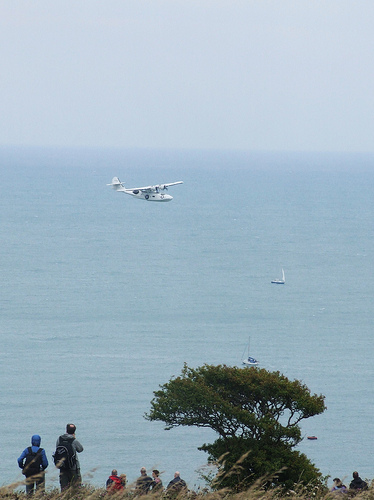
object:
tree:
[146, 357, 327, 447]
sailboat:
[270, 266, 287, 285]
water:
[1, 148, 371, 492]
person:
[14, 436, 46, 498]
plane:
[104, 174, 185, 206]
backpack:
[22, 445, 47, 478]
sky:
[1, 2, 371, 158]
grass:
[206, 485, 371, 498]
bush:
[195, 430, 321, 496]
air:
[1, 0, 371, 492]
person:
[51, 422, 87, 495]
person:
[349, 469, 368, 499]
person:
[151, 470, 163, 493]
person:
[135, 467, 151, 496]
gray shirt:
[55, 434, 82, 474]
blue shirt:
[15, 432, 49, 476]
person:
[105, 468, 122, 496]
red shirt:
[108, 476, 123, 492]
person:
[165, 469, 188, 499]